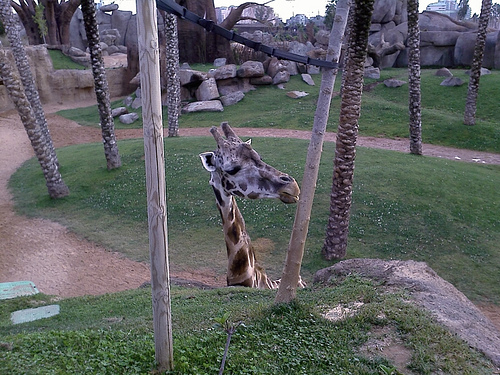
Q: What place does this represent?
A: It represents the zoo.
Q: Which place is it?
A: It is a zoo.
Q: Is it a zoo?
A: Yes, it is a zoo.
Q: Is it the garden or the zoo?
A: It is the zoo.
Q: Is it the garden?
A: No, it is the zoo.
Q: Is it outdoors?
A: Yes, it is outdoors.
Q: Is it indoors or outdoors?
A: It is outdoors.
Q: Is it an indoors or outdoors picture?
A: It is outdoors.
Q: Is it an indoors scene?
A: No, it is outdoors.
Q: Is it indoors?
A: No, it is outdoors.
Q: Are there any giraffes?
A: Yes, there is a giraffe.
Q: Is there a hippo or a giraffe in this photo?
A: Yes, there is a giraffe.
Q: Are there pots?
A: No, there are no pots.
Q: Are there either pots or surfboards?
A: No, there are no pots or surfboards.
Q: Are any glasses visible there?
A: No, there are no glasses.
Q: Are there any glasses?
A: No, there are no glasses.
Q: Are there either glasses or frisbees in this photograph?
A: No, there are no glasses or frisbees.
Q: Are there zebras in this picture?
A: No, there are no zebras.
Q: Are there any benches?
A: No, there are no benches.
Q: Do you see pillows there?
A: No, there are no pillows.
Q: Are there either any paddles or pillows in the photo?
A: No, there are no pillows or paddles.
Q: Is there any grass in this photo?
A: Yes, there is grass.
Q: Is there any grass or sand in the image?
A: Yes, there is grass.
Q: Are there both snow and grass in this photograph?
A: No, there is grass but no snow.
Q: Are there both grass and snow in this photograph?
A: No, there is grass but no snow.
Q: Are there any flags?
A: No, there are no flags.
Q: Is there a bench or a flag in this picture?
A: No, there are no flags or benches.